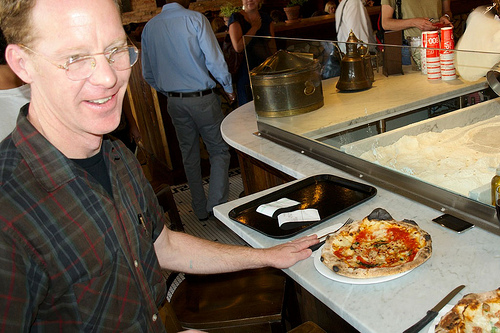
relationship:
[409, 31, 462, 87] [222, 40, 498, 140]
paper cups on counter top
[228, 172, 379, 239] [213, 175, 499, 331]
tray on counter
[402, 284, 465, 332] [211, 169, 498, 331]
knife on counter top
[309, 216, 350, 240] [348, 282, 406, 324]
fork on counter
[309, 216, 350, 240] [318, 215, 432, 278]
fork next to food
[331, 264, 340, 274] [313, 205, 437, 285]
burnt mark on pizza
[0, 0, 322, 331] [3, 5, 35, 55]
man has hair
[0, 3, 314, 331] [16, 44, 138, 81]
man wearing glasses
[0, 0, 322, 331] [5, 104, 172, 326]
man has shirt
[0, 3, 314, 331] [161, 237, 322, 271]
man has hand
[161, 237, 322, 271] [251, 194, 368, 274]
hand on fork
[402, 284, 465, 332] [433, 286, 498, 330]
knife next to pizza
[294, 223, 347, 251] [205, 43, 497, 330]
napkin on counter top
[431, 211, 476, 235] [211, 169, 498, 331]
cell phone on counter top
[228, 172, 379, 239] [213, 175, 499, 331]
tray sits on counter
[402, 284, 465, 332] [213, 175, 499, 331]
knife sits on counter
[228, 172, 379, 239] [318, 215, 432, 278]
tray and food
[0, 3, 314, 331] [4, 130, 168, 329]
man with plaid shirt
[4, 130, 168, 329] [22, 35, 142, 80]
plaid shirt wearing glasses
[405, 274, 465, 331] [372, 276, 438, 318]
knife laying on a counter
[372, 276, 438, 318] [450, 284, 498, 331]
counter next to pizza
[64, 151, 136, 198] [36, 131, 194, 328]
undershirt under a shirt